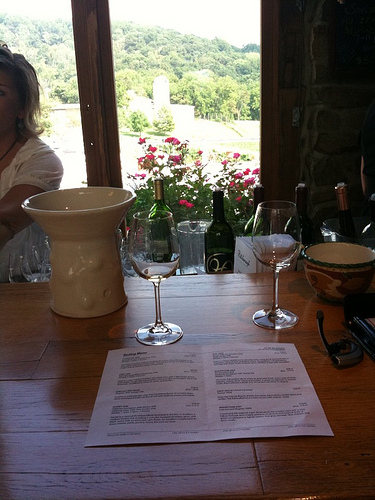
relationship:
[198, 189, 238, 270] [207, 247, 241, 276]
wine has lable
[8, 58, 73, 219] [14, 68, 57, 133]
woman has hair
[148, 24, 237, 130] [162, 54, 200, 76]
hill has trees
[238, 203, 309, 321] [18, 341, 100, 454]
wine glass on table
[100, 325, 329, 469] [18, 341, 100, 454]
menu on table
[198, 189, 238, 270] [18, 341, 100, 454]
wine on table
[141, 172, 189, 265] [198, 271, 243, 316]
wine bottle on talbe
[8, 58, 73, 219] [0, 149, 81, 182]
woman has shirt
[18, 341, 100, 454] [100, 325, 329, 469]
table has menu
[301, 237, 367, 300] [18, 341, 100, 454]
bowl on table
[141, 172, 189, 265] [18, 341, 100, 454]
wine bottle behind table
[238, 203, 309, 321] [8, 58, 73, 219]
wine glass beside woman